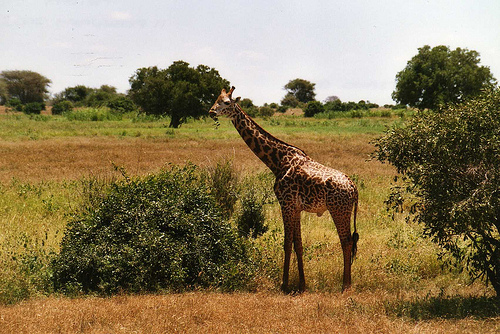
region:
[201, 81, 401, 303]
the giraffe is tall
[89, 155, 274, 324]
the bush is green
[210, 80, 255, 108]
the horns are two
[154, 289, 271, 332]
the grass is brown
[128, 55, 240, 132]
tree is in the background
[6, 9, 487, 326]
it is daytime in the photo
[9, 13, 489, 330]
the scene is in africa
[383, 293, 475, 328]
shadow is on the ground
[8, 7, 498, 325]
the scene is in the savannah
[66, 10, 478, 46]
the sky has no clouds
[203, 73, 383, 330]
Giraffe in the African plains.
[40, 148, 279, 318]
Bush that grows in Africa.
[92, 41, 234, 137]
Tree sitting by itself in the field.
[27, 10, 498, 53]
Clear skies in the distance.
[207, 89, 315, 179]
A long neck on a giraffe.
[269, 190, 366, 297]
Four legs on a giraffe.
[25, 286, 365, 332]
Dead, brown grass in the field.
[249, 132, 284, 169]
Spots on the giraffe's neck.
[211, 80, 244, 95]
Horns on the giraffe's head.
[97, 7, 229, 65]
Clouds in the distant sky.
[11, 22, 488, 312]
Lone giraffe standing in field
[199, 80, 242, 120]
Giraffe facing camera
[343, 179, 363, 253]
Brown long giraffe tail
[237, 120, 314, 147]
Brown mane on giraffe's back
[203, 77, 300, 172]
Long brown giraffe's neck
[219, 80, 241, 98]
Horn on giraffe's head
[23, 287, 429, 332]
Light brown grass field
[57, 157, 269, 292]
Mid high green bush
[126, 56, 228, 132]
Green tree in background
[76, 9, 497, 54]
Partly cloudy grey day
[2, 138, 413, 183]
a patch of dried brown grass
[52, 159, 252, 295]
a green leafy bush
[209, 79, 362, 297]
a giraffe standing in a grassy field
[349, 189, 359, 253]
the giraffe's tail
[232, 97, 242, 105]
the giraffe's ear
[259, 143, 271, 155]
a brown spot on the giraffe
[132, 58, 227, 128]
a tree with green leaves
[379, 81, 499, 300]
a green leafy bush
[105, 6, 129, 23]
solitary cloud in the sky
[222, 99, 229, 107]
the giraffe's eye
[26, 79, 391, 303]
a giraffe in front a bush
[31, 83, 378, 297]
a bush in front a giraffe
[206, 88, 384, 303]
giraffe face left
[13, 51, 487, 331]
a giraffe in a field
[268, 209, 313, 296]
long front legs of giraffe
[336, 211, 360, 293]
long back legs of giraffe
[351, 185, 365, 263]
a long tail with turf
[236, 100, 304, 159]
man of giraffe is long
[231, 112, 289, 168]
long neck of giraffe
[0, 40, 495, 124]
trees are in the background